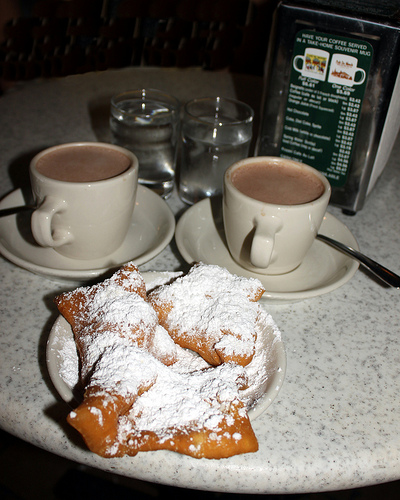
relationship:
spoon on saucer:
[318, 230, 399, 294] [169, 198, 358, 304]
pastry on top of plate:
[51, 261, 179, 385] [41, 268, 290, 426]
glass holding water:
[172, 94, 256, 208] [178, 118, 253, 208]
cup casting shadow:
[24, 143, 141, 261] [5, 142, 56, 207]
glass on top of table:
[172, 94, 256, 208] [3, 65, 398, 494]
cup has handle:
[24, 143, 141, 261] [29, 196, 70, 256]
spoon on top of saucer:
[318, 230, 399, 294] [169, 198, 358, 304]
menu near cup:
[275, 26, 373, 189] [24, 143, 141, 261]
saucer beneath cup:
[169, 198, 358, 304] [219, 155, 333, 279]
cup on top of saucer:
[219, 155, 333, 279] [169, 198, 358, 304]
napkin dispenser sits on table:
[252, 0, 398, 219] [3, 65, 398, 494]